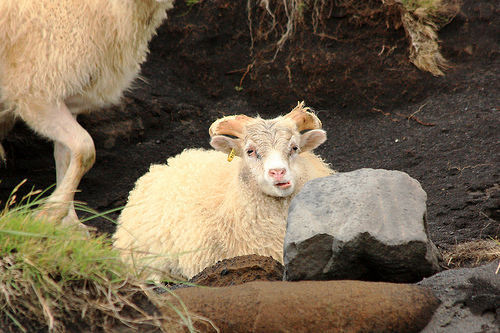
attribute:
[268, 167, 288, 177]
nose — pink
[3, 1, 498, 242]
dirt — wet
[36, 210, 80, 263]
grass — Small , patch 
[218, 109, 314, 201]
face — white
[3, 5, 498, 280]
ground — dirt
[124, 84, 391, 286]
sheep — white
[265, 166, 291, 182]
nose — pink